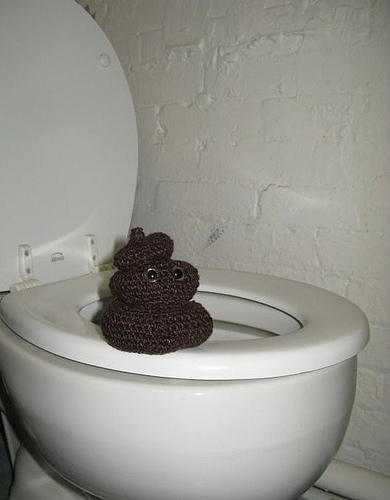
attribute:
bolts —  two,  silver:
[22, 248, 35, 285]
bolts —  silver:
[83, 233, 100, 272]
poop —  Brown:
[101, 219, 221, 362]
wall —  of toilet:
[135, 4, 388, 296]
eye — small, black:
[144, 266, 160, 282]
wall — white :
[262, 143, 352, 235]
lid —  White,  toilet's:
[29, 265, 387, 397]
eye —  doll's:
[147, 263, 159, 287]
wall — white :
[168, 70, 381, 241]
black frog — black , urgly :
[100, 235, 232, 325]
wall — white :
[312, 66, 369, 149]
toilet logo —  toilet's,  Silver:
[44, 248, 72, 264]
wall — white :
[82, 5, 388, 473]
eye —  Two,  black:
[146, 269, 157, 280]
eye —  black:
[170, 265, 183, 278]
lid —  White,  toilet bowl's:
[5, 247, 373, 382]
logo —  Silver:
[47, 252, 67, 264]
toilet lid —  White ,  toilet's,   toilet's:
[0, 0, 138, 295]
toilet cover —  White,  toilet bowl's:
[6, 2, 154, 293]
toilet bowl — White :
[2, 258, 376, 498]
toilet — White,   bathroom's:
[0, 0, 368, 498]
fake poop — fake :
[96, 222, 215, 358]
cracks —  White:
[133, 21, 354, 270]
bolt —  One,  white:
[100, 52, 111, 67]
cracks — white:
[212, 63, 281, 137]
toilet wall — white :
[199, 37, 360, 215]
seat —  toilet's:
[4, 80, 123, 230]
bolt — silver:
[90, 237, 101, 264]